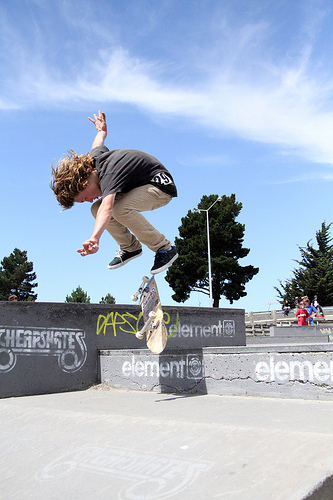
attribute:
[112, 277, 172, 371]
skateboard — midair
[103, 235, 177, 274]
shoes — black 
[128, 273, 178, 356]
skateboard — airborn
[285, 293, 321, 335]
people — walking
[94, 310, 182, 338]
graffiti — yellow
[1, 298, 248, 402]
wall — cement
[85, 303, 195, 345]
graffiti — yellow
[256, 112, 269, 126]
ground — skater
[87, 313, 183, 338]
grafitti — paint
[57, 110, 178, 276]
boy — midair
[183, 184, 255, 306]
pine tree — large, dark green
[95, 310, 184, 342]
graffiti — yellow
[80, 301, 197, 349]
graffiti — yellow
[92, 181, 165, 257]
pants — tan 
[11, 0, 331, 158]
clouds — white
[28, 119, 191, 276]
skateboarder — performing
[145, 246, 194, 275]
shoe — black 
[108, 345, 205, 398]
logo — white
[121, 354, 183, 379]
logo — element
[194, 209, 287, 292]
tree — green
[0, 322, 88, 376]
logo — cheapskats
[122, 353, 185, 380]
word — element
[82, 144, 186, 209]
shirt — black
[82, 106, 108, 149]
arm — raised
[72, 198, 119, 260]
arm — raised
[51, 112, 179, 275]
guy — brown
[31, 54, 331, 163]
cloud — white, whispy, cirrus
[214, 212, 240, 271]
leaves — green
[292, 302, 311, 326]
boy — white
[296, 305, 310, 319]
shirt — red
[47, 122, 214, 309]
boy — black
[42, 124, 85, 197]
hair — shaggy, curly, dark blond